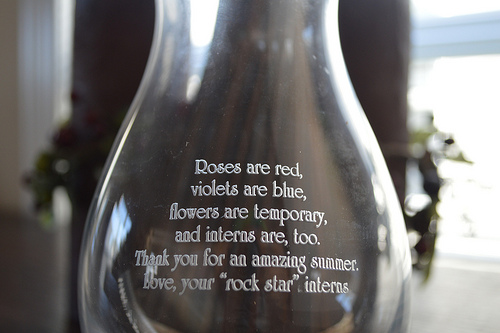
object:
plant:
[24, 104, 132, 232]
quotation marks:
[220, 271, 228, 279]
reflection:
[77, 0, 410, 333]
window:
[404, 54, 499, 269]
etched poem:
[131, 160, 359, 296]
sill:
[411, 251, 500, 276]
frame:
[403, 13, 499, 269]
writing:
[135, 157, 357, 297]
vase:
[76, 0, 416, 333]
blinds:
[0, 0, 73, 221]